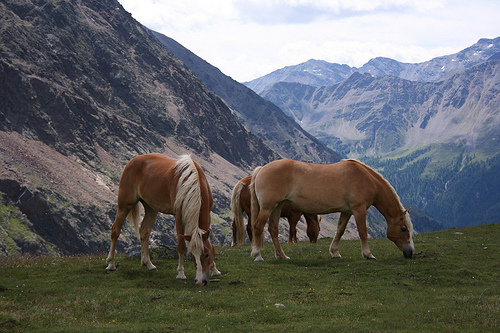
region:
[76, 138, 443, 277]
three horses in a pasture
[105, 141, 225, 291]
horse has white mane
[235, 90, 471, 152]
mountain ranges behind horses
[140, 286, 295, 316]
grass is lush and full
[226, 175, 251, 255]
horse's tail is white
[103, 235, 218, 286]
horse's hooves are white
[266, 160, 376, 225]
horse's body is tan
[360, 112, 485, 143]
snow on side of mountain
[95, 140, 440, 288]
three horses eating grass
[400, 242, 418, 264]
horse's nose is black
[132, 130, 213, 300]
the horse is eating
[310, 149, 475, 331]
the horse is eating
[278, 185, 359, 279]
the horse is eating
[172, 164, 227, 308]
the horse is eating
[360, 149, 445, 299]
the horse is eating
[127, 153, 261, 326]
the horse is brown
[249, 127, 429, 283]
the horse is brown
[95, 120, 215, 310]
the horse is brown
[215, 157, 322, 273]
the horse is brown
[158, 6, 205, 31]
white clouds in blue sky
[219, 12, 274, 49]
white clouds in blue sky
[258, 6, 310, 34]
white clouds in blue sky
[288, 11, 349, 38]
white clouds in blue sky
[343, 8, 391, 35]
white clouds in blue sky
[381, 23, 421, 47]
white clouds in blue sky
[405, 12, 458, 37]
white clouds in blue sky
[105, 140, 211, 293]
brown horse grazing on grass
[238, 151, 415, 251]
brown horse grazing on grass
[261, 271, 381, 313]
short green grass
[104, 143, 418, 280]
three light brown horses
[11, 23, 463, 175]
large mountains in the background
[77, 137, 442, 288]
three horses grazing on mountain side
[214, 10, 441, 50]
large white clouds covering sky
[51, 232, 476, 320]
patch of green grass on the mountain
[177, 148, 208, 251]
horses man is light brown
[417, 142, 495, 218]
green trees in valley of mountains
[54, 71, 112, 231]
dirt and rock on the mountains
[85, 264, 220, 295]
shadow of horse on ground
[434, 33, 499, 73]
white areas of snow on the mountain top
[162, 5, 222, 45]
white clouds in blue sky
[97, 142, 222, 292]
brown horse eating grass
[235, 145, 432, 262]
brown horse eating grass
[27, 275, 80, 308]
short green and brown grass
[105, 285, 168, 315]
short green and brown grass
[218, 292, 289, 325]
short green and brown grass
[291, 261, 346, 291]
short green and brown grass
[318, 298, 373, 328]
short green and brown grass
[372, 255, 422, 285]
short green and brown grass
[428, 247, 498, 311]
short green and brown grass